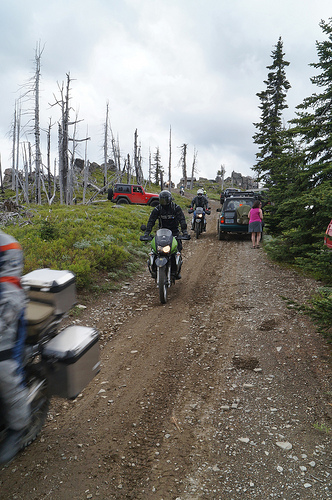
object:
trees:
[101, 100, 111, 193]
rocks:
[243, 383, 255, 389]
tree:
[18, 37, 48, 206]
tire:
[235, 205, 252, 225]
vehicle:
[216, 188, 264, 240]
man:
[190, 188, 209, 232]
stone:
[275, 440, 293, 451]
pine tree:
[287, 13, 331, 238]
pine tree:
[250, 36, 298, 240]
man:
[142, 189, 190, 280]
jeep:
[107, 182, 159, 207]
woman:
[248, 201, 264, 249]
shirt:
[249, 208, 262, 224]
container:
[19, 265, 74, 314]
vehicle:
[0, 262, 103, 469]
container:
[42, 322, 101, 399]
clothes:
[248, 208, 262, 233]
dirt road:
[0, 189, 332, 500]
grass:
[1, 159, 188, 299]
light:
[197, 214, 202, 218]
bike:
[185, 205, 211, 239]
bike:
[139, 224, 191, 303]